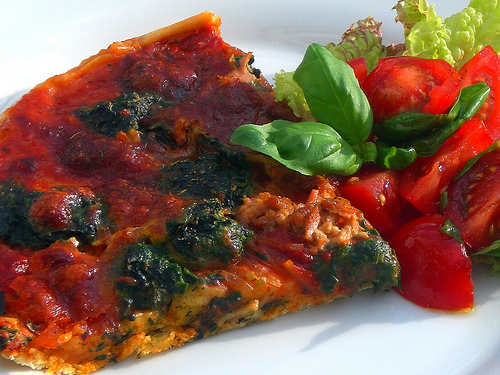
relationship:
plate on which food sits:
[229, 290, 437, 375] [91, 113, 469, 349]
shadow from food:
[298, 291, 488, 317] [312, 173, 437, 300]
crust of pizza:
[9, 51, 284, 123] [76, 182, 304, 375]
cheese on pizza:
[27, 196, 328, 333] [24, 101, 254, 364]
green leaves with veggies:
[118, 50, 444, 272] [283, 116, 359, 158]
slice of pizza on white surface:
[14, 50, 358, 317] [193, 318, 492, 375]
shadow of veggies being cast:
[198, 269, 499, 353] [250, 269, 443, 375]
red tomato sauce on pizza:
[7, 85, 191, 188] [45, 138, 301, 375]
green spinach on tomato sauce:
[134, 173, 212, 307] [76, 227, 284, 348]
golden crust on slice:
[70, 50, 119, 95] [12, 102, 222, 247]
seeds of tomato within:
[454, 164, 494, 207] [452, 159, 498, 242]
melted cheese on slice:
[154, 243, 300, 335] [23, 214, 338, 375]